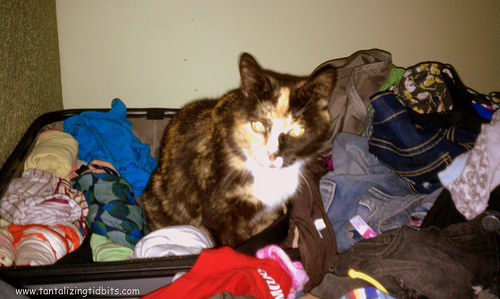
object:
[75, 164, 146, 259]
clothing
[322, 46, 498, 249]
clothes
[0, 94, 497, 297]
bed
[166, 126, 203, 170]
fur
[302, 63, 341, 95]
ear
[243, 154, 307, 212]
spot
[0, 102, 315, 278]
chest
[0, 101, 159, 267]
clothing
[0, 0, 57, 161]
wall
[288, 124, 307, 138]
eye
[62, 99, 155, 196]
clothing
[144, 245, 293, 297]
shirt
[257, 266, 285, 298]
text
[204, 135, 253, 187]
whiskers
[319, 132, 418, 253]
jeans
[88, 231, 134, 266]
clothing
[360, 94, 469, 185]
clothing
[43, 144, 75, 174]
yellow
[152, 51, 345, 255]
cat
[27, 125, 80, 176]
clothing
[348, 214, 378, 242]
tag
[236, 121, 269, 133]
eye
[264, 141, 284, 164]
nose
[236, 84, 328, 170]
face